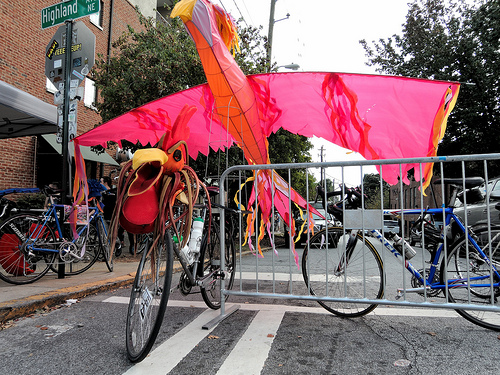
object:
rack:
[219, 151, 499, 318]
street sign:
[38, 0, 103, 275]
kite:
[49, 0, 475, 267]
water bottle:
[388, 227, 418, 260]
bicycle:
[300, 176, 499, 331]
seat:
[434, 176, 485, 190]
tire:
[126, 229, 172, 363]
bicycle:
[126, 153, 239, 360]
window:
[80, 75, 99, 105]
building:
[0, 0, 179, 242]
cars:
[453, 173, 499, 251]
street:
[1, 228, 498, 374]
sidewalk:
[0, 233, 293, 329]